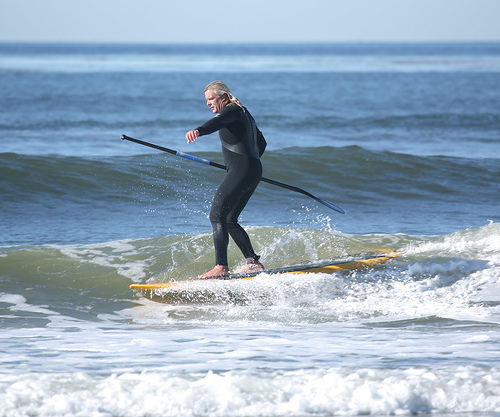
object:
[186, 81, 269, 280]
man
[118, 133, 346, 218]
paddle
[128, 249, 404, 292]
surfboard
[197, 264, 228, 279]
foot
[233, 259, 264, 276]
foot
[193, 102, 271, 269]
wetsuit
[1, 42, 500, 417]
ocean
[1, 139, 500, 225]
wave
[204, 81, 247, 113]
hair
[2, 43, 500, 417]
water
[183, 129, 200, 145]
hand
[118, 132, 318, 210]
pole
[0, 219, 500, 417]
foamy area